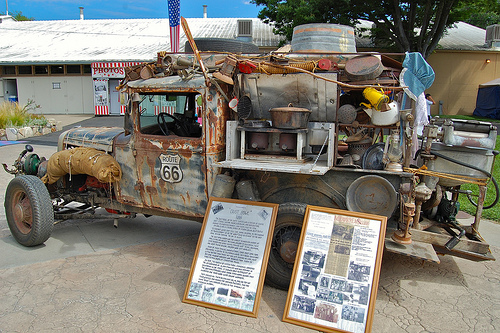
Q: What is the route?
A: 66.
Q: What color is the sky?
A: Blue.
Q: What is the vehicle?
A: A truck.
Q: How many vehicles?
A: One.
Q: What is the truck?
A: An antique.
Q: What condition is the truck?
A: Old.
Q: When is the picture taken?
A: Daytime.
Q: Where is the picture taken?
A: Near old truck.